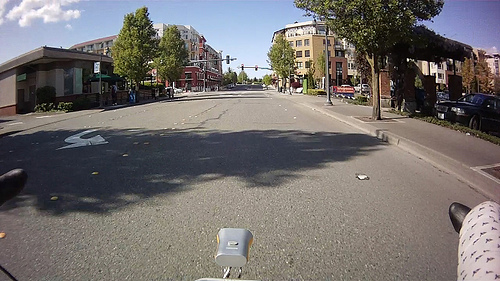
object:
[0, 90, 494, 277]
street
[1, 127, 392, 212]
shadow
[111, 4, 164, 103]
tree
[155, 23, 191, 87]
tree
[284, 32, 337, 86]
building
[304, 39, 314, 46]
window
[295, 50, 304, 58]
window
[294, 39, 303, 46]
window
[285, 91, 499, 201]
sidewalk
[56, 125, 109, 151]
arrow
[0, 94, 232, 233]
lane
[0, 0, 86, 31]
cloud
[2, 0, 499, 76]
sky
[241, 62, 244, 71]
signal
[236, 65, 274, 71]
post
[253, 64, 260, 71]
signal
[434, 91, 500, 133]
truck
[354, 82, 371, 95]
hatchback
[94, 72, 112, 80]
awning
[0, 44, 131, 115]
building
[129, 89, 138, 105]
trashcan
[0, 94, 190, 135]
sidewalk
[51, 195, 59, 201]
reflector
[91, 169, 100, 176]
reflector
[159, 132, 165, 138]
reflector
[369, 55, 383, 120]
trunk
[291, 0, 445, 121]
tree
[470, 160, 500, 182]
part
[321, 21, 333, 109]
lamp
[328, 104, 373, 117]
part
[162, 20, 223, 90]
building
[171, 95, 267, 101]
shadow